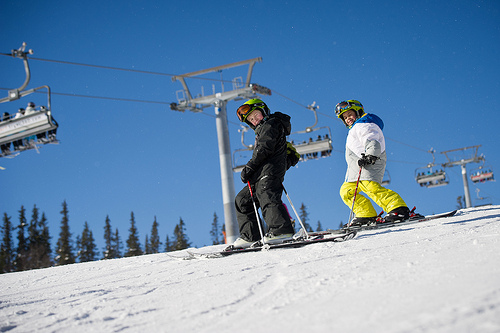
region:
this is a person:
[227, 85, 314, 242]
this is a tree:
[6, 200, 44, 285]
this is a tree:
[170, 211, 192, 251]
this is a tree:
[140, 206, 163, 257]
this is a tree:
[115, 203, 146, 256]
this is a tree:
[95, 210, 121, 265]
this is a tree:
[71, 215, 97, 257]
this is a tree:
[40, 193, 73, 263]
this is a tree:
[24, 197, 54, 272]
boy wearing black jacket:
[207, 72, 312, 262]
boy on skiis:
[215, 81, 308, 268]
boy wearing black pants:
[211, 84, 316, 258]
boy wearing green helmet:
[189, 72, 312, 247]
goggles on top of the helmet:
[230, 93, 269, 138]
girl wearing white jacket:
[317, 85, 417, 227]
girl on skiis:
[321, 87, 419, 235]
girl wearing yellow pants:
[330, 87, 405, 239]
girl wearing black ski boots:
[322, 79, 424, 237]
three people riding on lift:
[6, 82, 67, 158]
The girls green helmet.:
[322, 91, 370, 114]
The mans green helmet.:
[232, 93, 272, 130]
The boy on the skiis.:
[220, 95, 297, 243]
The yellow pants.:
[340, 176, 407, 213]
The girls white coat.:
[339, 128, 399, 183]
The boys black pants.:
[233, 177, 293, 241]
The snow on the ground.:
[81, 273, 478, 331]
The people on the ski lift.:
[0, 103, 44, 150]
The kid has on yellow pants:
[336, 165, 412, 217]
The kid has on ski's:
[167, 223, 358, 263]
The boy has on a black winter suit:
[232, 115, 300, 235]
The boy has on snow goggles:
[228, 97, 273, 124]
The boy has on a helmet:
[235, 94, 272, 131]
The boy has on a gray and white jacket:
[343, 108, 392, 188]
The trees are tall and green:
[0, 199, 195, 274]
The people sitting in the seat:
[0, 40, 64, 165]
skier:
[220, 71, 280, 241]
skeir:
[328, 86, 390, 266]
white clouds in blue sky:
[82, 128, 140, 182]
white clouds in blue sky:
[355, 9, 385, 43]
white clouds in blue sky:
[248, 28, 293, 48]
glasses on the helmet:
[239, 97, 266, 117]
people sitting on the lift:
[3, 101, 56, 148]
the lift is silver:
[6, 117, 53, 139]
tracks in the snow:
[56, 280, 198, 332]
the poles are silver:
[247, 180, 299, 241]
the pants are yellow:
[343, 182, 389, 222]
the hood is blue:
[362, 110, 389, 135]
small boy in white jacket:
[335, 95, 422, 235]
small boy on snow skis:
[330, 91, 412, 230]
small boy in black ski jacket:
[222, 92, 314, 248]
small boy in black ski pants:
[228, 95, 309, 255]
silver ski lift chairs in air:
[0, 38, 499, 185]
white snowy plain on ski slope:
[1, 196, 498, 326]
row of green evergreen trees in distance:
[0, 172, 463, 272]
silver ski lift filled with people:
[417, 162, 454, 189]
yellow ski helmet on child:
[236, 96, 273, 131]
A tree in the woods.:
[120, 211, 145, 255]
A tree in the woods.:
[144, 215, 165, 256]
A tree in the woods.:
[170, 217, 187, 252]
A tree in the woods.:
[211, 210, 222, 246]